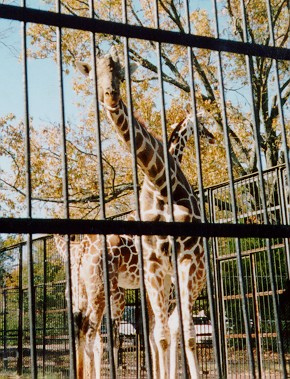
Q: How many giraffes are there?
A: Two.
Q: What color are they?
A: Brown and white.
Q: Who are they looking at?
A: Visitors.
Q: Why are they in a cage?
A: They are at the zoo.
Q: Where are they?
A: In the zoo.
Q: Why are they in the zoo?
A: So people can see them.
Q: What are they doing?
A: Looking out of the cage.